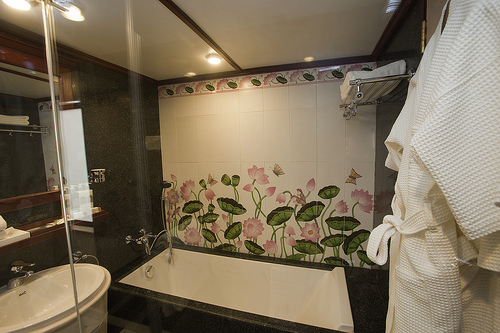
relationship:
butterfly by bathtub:
[263, 157, 316, 194] [122, 224, 382, 313]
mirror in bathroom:
[8, 27, 98, 229] [27, 44, 379, 285]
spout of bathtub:
[144, 216, 169, 262] [122, 224, 382, 313]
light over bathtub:
[201, 38, 249, 83] [122, 224, 382, 313]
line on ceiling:
[167, 7, 258, 69] [98, 14, 381, 79]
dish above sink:
[1, 218, 28, 237] [17, 265, 129, 332]